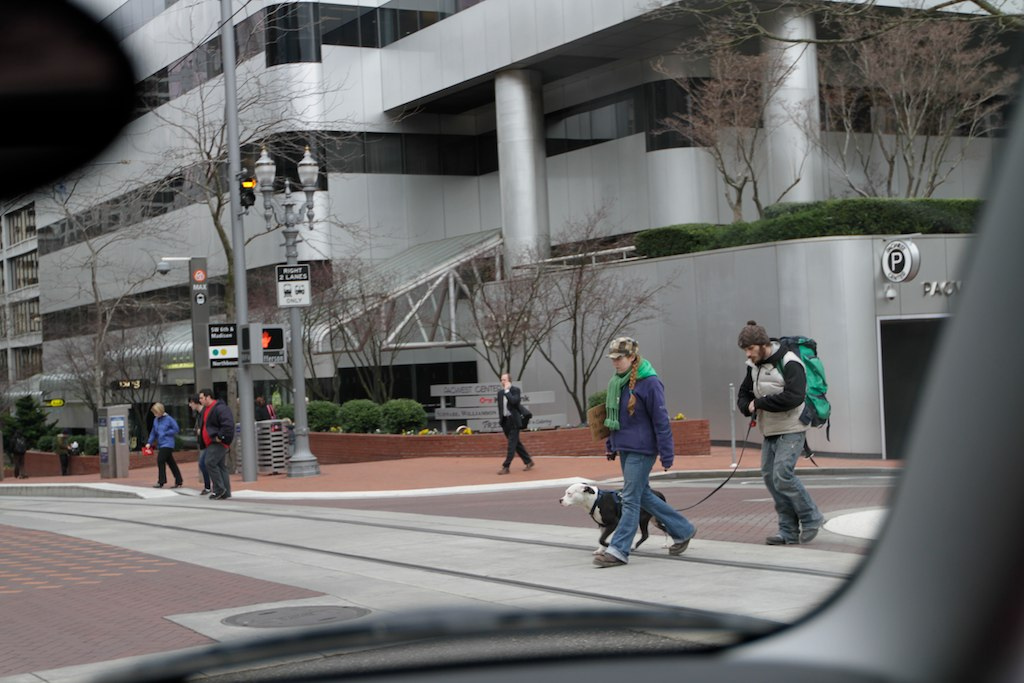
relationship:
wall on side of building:
[326, 171, 495, 288] [8, 9, 1020, 483]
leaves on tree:
[417, 396, 431, 410] [371, 385, 432, 435]